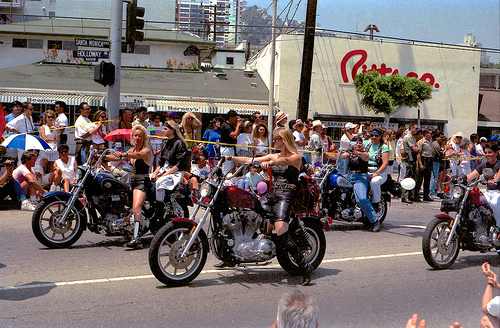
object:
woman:
[212, 127, 315, 287]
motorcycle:
[148, 137, 327, 287]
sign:
[338, 49, 442, 89]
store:
[254, 33, 486, 148]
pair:
[481, 259, 499, 288]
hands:
[480, 260, 496, 277]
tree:
[353, 68, 434, 130]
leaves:
[376, 85, 392, 92]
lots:
[355, 68, 434, 115]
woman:
[93, 124, 154, 250]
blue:
[15, 138, 23, 145]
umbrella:
[1, 133, 51, 152]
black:
[125, 7, 133, 44]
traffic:
[125, 1, 148, 46]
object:
[360, 23, 382, 41]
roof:
[476, 87, 499, 127]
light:
[133, 5, 146, 19]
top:
[0, 61, 277, 105]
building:
[0, 59, 276, 117]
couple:
[339, 127, 391, 232]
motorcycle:
[304, 141, 393, 229]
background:
[0, 0, 499, 328]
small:
[353, 67, 434, 131]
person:
[27, 149, 62, 193]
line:
[2, 247, 437, 291]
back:
[276, 288, 320, 327]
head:
[276, 288, 320, 327]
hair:
[275, 288, 321, 327]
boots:
[275, 229, 315, 288]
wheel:
[148, 220, 211, 288]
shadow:
[1, 280, 57, 301]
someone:
[0, 144, 35, 211]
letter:
[340, 50, 367, 83]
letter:
[417, 72, 435, 87]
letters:
[376, 62, 392, 78]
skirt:
[129, 174, 153, 196]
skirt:
[258, 183, 297, 224]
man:
[271, 285, 321, 327]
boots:
[126, 220, 147, 248]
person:
[147, 119, 192, 224]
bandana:
[161, 121, 177, 131]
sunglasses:
[270, 135, 283, 141]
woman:
[466, 142, 500, 230]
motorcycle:
[420, 166, 499, 270]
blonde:
[212, 126, 325, 287]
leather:
[288, 242, 296, 251]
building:
[244, 33, 481, 143]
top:
[280, 284, 317, 310]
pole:
[106, 1, 122, 133]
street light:
[133, 28, 145, 42]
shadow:
[154, 266, 343, 290]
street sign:
[92, 59, 115, 86]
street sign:
[73, 37, 112, 49]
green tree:
[351, 69, 434, 123]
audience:
[395, 123, 420, 205]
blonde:
[96, 124, 152, 226]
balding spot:
[290, 299, 307, 309]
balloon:
[255, 180, 269, 196]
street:
[0, 198, 499, 327]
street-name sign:
[72, 49, 109, 63]